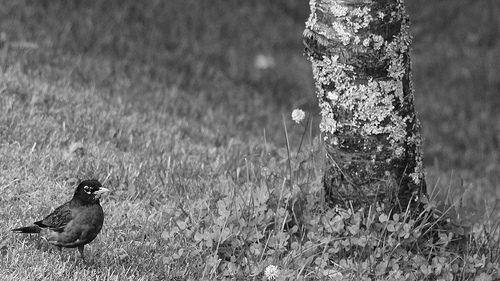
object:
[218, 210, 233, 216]
flower leaves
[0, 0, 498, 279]
grass ground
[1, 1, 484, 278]
grass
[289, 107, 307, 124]
flower blossom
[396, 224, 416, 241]
clovers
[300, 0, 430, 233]
tree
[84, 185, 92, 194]
eye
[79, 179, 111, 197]
bird's face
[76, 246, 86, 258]
legs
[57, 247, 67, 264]
leg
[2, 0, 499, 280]
ground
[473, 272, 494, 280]
leaves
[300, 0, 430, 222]
bark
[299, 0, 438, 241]
tree trunk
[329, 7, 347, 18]
moss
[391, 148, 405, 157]
moss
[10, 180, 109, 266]
bird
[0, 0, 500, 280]
field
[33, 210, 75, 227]
wing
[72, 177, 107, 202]
head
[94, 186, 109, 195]
beak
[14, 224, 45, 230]
feathers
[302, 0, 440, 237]
tree stump